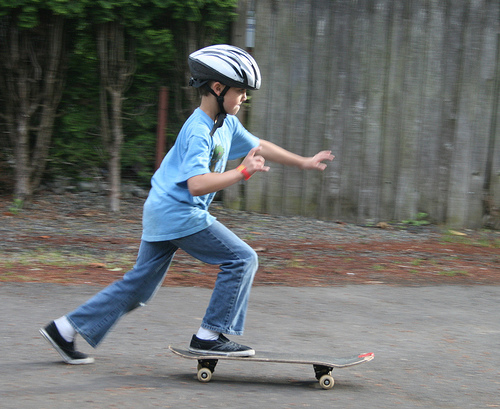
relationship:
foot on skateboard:
[171, 312, 267, 362] [184, 322, 261, 366]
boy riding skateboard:
[34, 42, 335, 369] [161, 325, 378, 393]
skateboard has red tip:
[161, 325, 378, 393] [357, 345, 385, 373]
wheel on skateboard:
[188, 362, 219, 385] [161, 325, 378, 393]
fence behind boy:
[272, 19, 496, 142] [34, 37, 337, 392]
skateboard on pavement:
[161, 325, 378, 393] [186, 384, 343, 405]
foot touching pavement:
[47, 340, 102, 373] [53, 365, 110, 384]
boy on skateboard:
[34, 37, 337, 392] [161, 325, 378, 393]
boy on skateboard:
[34, 42, 335, 369] [161, 325, 378, 393]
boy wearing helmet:
[34, 37, 337, 392] [159, 18, 279, 108]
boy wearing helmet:
[34, 42, 335, 369] [159, 18, 279, 108]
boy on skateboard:
[34, 42, 335, 369] [165, 339, 377, 393]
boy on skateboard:
[34, 42, 335, 369] [160, 337, 380, 391]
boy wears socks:
[34, 42, 335, 369] [50, 312, 220, 344]